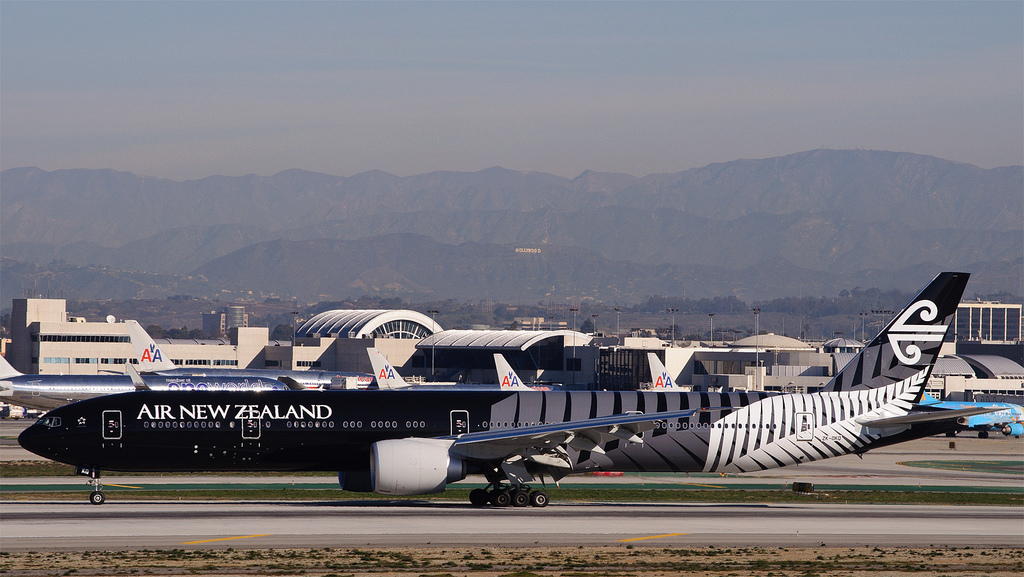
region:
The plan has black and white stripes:
[84, 268, 970, 496]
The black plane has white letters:
[11, 313, 517, 517]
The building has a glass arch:
[231, 234, 661, 427]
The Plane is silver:
[27, 296, 474, 414]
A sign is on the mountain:
[424, 168, 778, 342]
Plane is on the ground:
[8, 251, 1015, 511]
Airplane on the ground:
[8, 256, 1015, 516]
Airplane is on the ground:
[10, 257, 1019, 526]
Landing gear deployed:
[62, 447, 569, 524]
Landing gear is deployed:
[73, 465, 560, 514]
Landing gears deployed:
[64, 460, 555, 512]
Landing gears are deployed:
[68, 462, 574, 520]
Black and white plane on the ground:
[10, 244, 1001, 516]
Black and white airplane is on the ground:
[14, 247, 1010, 516]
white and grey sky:
[323, 22, 602, 128]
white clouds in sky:
[345, 27, 595, 157]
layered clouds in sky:
[389, 55, 590, 154]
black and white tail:
[798, 281, 970, 427]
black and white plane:
[42, 417, 922, 494]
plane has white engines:
[360, 429, 481, 515]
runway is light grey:
[1, 512, 461, 551]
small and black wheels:
[57, 471, 141, 516]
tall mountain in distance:
[342, 132, 1022, 314]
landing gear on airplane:
[463, 470, 552, 513]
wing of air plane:
[435, 401, 731, 449]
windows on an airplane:
[133, 411, 432, 440]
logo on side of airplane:
[134, 392, 335, 424]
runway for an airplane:
[200, 506, 561, 548]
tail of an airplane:
[832, 274, 988, 410]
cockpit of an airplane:
[35, 405, 83, 459]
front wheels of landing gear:
[76, 462, 108, 505]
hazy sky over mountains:
[324, 51, 574, 141]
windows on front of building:
[359, 316, 442, 336]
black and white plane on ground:
[7, 279, 995, 537]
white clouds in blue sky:
[168, 83, 232, 134]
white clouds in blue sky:
[511, 110, 578, 142]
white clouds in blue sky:
[638, 160, 708, 211]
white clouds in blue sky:
[439, 116, 479, 148]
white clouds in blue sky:
[285, 34, 381, 134]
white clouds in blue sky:
[170, 48, 259, 122]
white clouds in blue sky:
[651, 63, 706, 134]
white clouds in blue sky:
[750, 111, 824, 159]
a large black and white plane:
[13, 209, 1000, 522]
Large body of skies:
[54, 4, 209, 113]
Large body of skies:
[239, 22, 464, 143]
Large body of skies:
[521, 19, 719, 128]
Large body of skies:
[269, 13, 536, 109]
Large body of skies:
[688, 10, 984, 124]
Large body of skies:
[37, 23, 234, 147]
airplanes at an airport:
[112, 311, 840, 562]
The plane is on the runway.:
[44, 297, 961, 533]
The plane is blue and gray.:
[28, 360, 953, 471]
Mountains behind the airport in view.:
[68, 108, 934, 308]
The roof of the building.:
[293, 288, 450, 356]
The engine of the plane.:
[369, 424, 465, 488]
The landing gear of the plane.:
[445, 470, 560, 505]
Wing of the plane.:
[457, 407, 707, 450]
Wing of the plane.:
[449, 398, 740, 459]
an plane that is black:
[46, 303, 976, 525]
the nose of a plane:
[14, 397, 75, 475]